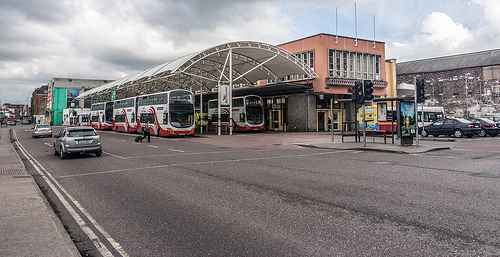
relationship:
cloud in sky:
[100, 30, 136, 56] [307, 13, 338, 29]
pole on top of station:
[331, 6, 340, 40] [273, 31, 391, 132]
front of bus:
[168, 91, 194, 130] [138, 87, 197, 136]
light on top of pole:
[354, 82, 365, 101] [357, 106, 360, 145]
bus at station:
[138, 87, 197, 136] [281, 36, 391, 95]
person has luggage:
[132, 119, 154, 143] [134, 131, 143, 145]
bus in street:
[138, 87, 197, 136] [310, 152, 409, 180]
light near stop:
[354, 82, 365, 101] [303, 134, 342, 147]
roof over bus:
[73, 44, 316, 92] [138, 87, 197, 136]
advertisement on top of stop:
[355, 105, 376, 129] [303, 134, 342, 147]